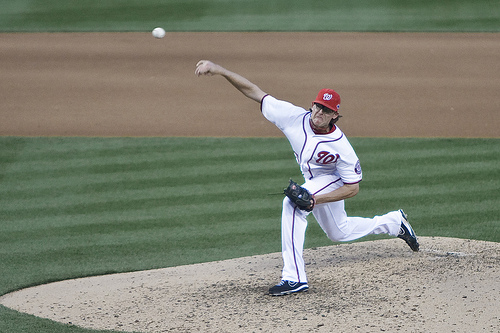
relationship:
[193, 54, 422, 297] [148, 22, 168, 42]
man throwing baseball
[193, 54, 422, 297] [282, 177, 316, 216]
man wearing glove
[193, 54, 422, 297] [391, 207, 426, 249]
man wearing shoe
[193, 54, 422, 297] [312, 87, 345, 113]
man wearing hat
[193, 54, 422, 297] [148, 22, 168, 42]
man playing baseball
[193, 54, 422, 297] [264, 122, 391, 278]
man in uniform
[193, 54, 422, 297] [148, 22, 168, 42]
pitcher throwing baseball